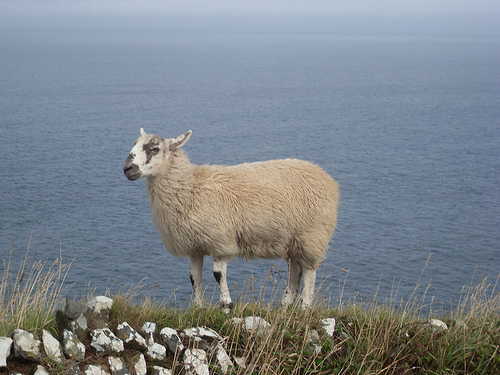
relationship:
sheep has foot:
[121, 125, 338, 319] [216, 301, 238, 320]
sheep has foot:
[121, 125, 338, 319] [298, 303, 314, 317]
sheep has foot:
[121, 125, 338, 319] [277, 301, 292, 314]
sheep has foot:
[121, 125, 338, 319] [192, 302, 209, 316]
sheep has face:
[121, 125, 338, 319] [119, 133, 169, 185]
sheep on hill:
[121, 125, 338, 319] [1, 301, 498, 374]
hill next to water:
[1, 301, 498, 374] [3, 33, 500, 314]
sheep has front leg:
[124, 125, 344, 320] [189, 248, 208, 317]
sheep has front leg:
[124, 125, 344, 320] [212, 255, 236, 316]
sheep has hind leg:
[124, 125, 344, 320] [300, 257, 318, 312]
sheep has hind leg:
[124, 125, 344, 320] [279, 255, 304, 308]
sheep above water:
[124, 125, 344, 320] [3, 33, 500, 314]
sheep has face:
[124, 125, 344, 320] [119, 133, 169, 185]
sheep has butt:
[124, 125, 344, 320] [307, 159, 344, 222]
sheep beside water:
[124, 125, 344, 320] [3, 33, 500, 314]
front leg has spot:
[189, 248, 208, 317] [188, 271, 199, 287]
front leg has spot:
[212, 255, 236, 316] [213, 269, 224, 285]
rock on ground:
[35, 328, 67, 366] [4, 308, 499, 374]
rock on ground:
[89, 327, 128, 355] [4, 308, 499, 374]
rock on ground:
[75, 294, 115, 334] [4, 308, 499, 374]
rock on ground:
[179, 326, 227, 351] [4, 308, 499, 374]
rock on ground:
[160, 324, 186, 356] [4, 308, 499, 374]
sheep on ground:
[124, 125, 344, 320] [4, 308, 499, 374]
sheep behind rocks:
[124, 125, 344, 320] [1, 294, 336, 375]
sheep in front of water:
[124, 125, 344, 320] [3, 33, 500, 314]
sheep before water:
[124, 125, 344, 320] [3, 33, 500, 314]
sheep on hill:
[124, 125, 344, 320] [1, 301, 498, 374]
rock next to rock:
[179, 326, 227, 351] [160, 324, 186, 356]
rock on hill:
[426, 316, 449, 335] [1, 301, 498, 374]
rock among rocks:
[179, 326, 227, 351] [1, 294, 336, 375]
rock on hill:
[306, 329, 322, 356] [1, 301, 498, 374]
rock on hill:
[179, 326, 227, 351] [1, 301, 498, 374]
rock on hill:
[89, 327, 128, 355] [1, 301, 498, 374]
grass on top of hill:
[4, 230, 340, 375] [1, 301, 498, 374]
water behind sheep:
[3, 33, 500, 314] [124, 125, 344, 320]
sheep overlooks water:
[124, 125, 344, 320] [3, 33, 500, 314]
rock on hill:
[35, 328, 67, 366] [1, 301, 498, 374]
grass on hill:
[4, 230, 340, 375] [1, 301, 498, 374]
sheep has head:
[124, 125, 344, 320] [123, 126, 193, 184]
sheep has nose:
[124, 125, 344, 320] [121, 163, 134, 174]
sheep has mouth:
[124, 125, 344, 320] [128, 172, 141, 181]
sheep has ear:
[124, 125, 344, 320] [170, 128, 196, 151]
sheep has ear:
[124, 125, 344, 320] [138, 126, 147, 137]